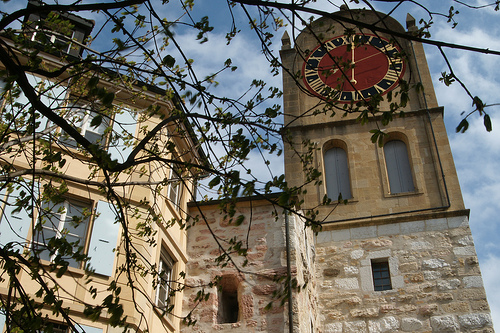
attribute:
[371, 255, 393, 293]
window — glass, framed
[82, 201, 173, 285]
shutter — white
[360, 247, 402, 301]
window — very small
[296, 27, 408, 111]
clock — large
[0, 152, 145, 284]
shutter — white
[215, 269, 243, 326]
window — small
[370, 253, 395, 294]
window — small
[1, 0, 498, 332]
sky — blue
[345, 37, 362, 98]
hand — gold, hour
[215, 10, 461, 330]
building — multi story, tan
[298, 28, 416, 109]
clock — large, black red and off-white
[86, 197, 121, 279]
window shutter — baby blue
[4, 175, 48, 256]
window shutter — baby blue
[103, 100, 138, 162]
window shutter — baby blue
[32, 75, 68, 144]
window shutter — baby blue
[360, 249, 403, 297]
window — open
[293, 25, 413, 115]
red clock — big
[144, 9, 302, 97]
sky — blue, cloudy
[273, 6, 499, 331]
tower — stone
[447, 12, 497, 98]
sky — blue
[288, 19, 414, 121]
clock — large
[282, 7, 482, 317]
tower — large, stone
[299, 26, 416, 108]
outside clock — large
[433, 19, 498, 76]
cloud — small, thin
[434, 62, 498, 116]
cloud — small, thin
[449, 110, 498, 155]
cloud — small, thin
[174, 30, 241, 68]
cloud — small, thin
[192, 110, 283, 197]
cloud — small, thin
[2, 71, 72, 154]
shutter — white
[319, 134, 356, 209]
window — long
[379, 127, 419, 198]
window — long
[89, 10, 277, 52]
streak — thin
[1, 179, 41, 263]
shutter — white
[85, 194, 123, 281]
shutter — white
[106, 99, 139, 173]
shutter — white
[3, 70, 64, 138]
shutter — white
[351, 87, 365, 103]
roman numeral — white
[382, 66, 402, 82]
roman numeral — white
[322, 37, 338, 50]
roman numeral — white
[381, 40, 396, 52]
roman numeral — white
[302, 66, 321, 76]
roman numeral — white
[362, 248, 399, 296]
frame — brown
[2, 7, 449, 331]
outside — large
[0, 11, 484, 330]
building — stone, large, tan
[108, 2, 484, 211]
clouds — white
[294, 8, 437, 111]
clock — large